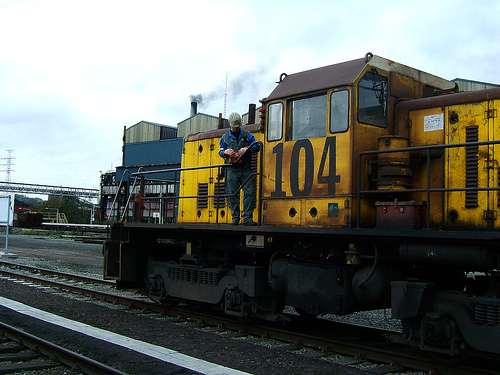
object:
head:
[227, 111, 243, 133]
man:
[221, 111, 263, 224]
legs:
[226, 168, 258, 225]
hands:
[226, 147, 247, 157]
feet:
[229, 212, 260, 227]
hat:
[228, 111, 242, 126]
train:
[98, 54, 498, 356]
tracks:
[0, 262, 500, 375]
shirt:
[218, 132, 260, 168]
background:
[4, 3, 106, 242]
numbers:
[271, 143, 341, 197]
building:
[99, 99, 215, 219]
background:
[0, 0, 121, 259]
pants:
[226, 167, 254, 217]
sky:
[1, 2, 500, 188]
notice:
[425, 114, 444, 132]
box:
[376, 200, 427, 229]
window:
[261, 77, 394, 142]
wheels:
[140, 270, 500, 364]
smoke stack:
[187, 166, 196, 182]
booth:
[266, 51, 413, 227]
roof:
[273, 55, 370, 92]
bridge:
[1, 180, 99, 199]